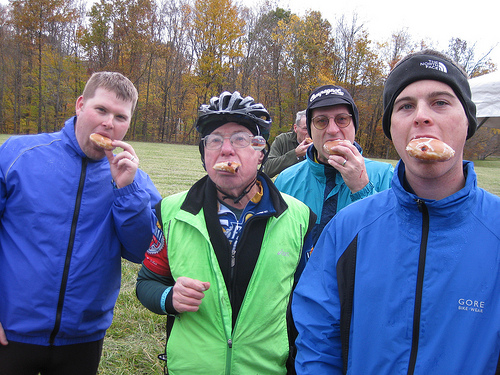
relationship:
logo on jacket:
[424, 290, 493, 330] [366, 182, 475, 358]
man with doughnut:
[349, 61, 496, 323] [199, 144, 267, 197]